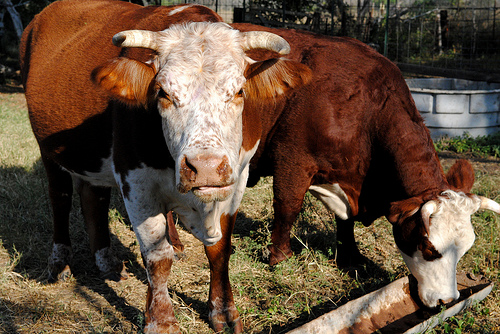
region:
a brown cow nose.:
[171, 137, 241, 203]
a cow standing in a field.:
[237, 25, 484, 325]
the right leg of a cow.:
[117, 183, 200, 330]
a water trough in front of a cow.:
[289, 245, 495, 331]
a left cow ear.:
[241, 51, 301, 128]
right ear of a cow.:
[86, 54, 174, 100]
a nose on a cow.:
[172, 148, 246, 194]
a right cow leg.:
[136, 248, 188, 332]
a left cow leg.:
[194, 233, 251, 330]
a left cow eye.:
[226, 78, 255, 105]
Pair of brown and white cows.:
[20, 0, 498, 332]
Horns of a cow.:
[110, 23, 294, 59]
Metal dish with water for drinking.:
[264, 268, 495, 333]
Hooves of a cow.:
[207, 309, 247, 332]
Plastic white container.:
[393, 73, 498, 144]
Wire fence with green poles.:
[208, 0, 498, 77]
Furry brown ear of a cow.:
[89, 56, 160, 112]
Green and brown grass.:
[1, 93, 498, 333]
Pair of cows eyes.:
[150, 78, 250, 112]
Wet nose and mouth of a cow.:
[170, 151, 240, 201]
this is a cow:
[0, 5, 294, 332]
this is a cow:
[265, 9, 497, 330]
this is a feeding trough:
[291, 245, 496, 330]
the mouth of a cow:
[184, 132, 239, 207]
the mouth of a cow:
[422, 285, 479, 329]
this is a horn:
[411, 175, 445, 252]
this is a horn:
[465, 191, 495, 239]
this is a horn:
[227, 11, 305, 98]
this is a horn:
[108, 16, 170, 74]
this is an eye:
[222, 65, 260, 110]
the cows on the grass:
[24, 3, 464, 308]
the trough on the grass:
[287, 263, 494, 331]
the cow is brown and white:
[13, 3, 281, 307]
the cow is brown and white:
[224, 20, 481, 305]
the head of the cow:
[90, 11, 318, 216]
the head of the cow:
[370, 147, 491, 328]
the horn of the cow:
[104, 28, 163, 63]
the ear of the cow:
[88, 58, 155, 100]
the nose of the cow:
[181, 150, 226, 183]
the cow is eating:
[251, 21, 498, 302]